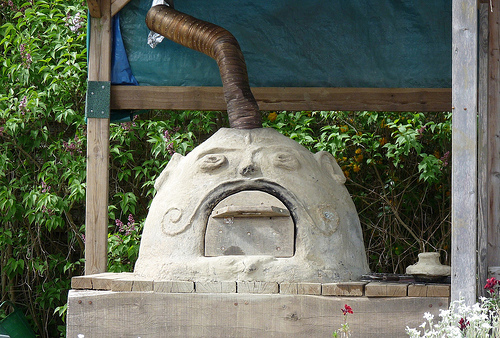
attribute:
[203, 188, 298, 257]
door — grey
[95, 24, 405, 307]
oven — outdoor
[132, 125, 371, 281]
oven — composed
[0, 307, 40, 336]
urn — green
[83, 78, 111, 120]
bracket — green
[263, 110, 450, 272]
trees — fruit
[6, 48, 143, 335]
bush — lilac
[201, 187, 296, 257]
oven — shaped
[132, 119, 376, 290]
oven — outdoor, large, wood-fired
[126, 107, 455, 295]
oven — sculpted, outdoor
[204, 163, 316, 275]
oven — outdoor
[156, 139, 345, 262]
face — sculpted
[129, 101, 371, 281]
oven — outdoor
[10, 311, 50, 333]
bucket — green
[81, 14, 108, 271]
post — wooden, green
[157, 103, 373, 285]
oven — carved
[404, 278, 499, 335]
flowers — white, burgandy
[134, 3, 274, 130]
pipe — exhaust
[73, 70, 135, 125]
clamp — metal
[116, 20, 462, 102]
tarp — blue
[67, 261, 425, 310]
boards — wooden